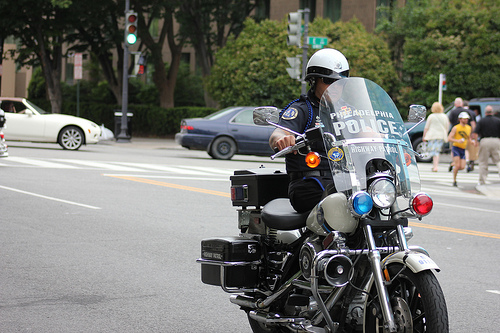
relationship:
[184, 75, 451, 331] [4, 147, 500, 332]
motorcycle on road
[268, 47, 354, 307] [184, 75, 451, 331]
man on motorcycle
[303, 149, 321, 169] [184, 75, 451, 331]
light on motorcycle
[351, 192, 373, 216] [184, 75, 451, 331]
blue light on motorcycle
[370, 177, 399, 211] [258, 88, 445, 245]
light on motorcycle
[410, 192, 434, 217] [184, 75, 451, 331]
light on motorcycle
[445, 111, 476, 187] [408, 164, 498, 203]
person on sidewalk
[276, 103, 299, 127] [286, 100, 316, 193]
patch on uniform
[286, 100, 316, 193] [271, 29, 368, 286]
uniform of man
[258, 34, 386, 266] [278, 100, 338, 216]
man dressed in uniform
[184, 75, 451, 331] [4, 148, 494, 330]
motorcycle on road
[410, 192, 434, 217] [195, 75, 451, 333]
light on motorcycle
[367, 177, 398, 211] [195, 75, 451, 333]
light on motorcycle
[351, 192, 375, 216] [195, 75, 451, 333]
blue light on motorcycle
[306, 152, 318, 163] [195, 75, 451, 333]
light on motorcycle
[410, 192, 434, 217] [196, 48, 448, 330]
light on bike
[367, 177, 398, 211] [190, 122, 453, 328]
light on bike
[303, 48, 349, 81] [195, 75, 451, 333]
helmet on motorcycle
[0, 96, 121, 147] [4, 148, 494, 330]
car on road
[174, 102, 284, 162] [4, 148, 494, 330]
car on road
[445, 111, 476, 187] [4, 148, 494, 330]
person on road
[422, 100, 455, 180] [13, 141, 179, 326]
person on road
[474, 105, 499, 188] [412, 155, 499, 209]
person on road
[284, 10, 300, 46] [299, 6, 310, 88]
signal on pole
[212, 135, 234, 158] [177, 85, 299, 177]
tire on care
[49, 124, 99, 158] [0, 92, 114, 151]
tire on car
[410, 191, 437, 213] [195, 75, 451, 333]
light on motorcycle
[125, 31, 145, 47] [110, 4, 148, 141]
light on signal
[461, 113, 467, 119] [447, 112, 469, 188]
hat on person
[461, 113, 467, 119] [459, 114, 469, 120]
hat on head